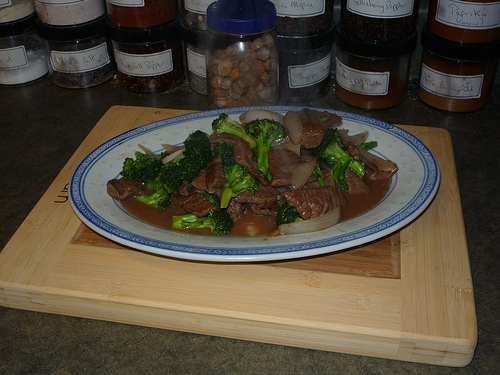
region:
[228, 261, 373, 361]
the board is brown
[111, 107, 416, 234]
the food is cooked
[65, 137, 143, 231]
the plate is blue and white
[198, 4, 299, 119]
the jar is closed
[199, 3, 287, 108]
the jar is full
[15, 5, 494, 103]
there are many jars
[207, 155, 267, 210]
the veggie is green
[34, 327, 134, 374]
the counter is green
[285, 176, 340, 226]
the beef is brown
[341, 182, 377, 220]
the liquid is brown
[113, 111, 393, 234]
food, meat and vegetables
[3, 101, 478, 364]
wooden cutting board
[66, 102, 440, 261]
white plate with blue trim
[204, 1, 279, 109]
jar with orange rocks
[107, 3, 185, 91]
jar with red lid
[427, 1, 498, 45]
jar with label that says paprika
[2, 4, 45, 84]
jar of salt on the far left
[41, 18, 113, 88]
jar second from left that says black salt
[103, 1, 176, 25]
jar third from right with red powder inside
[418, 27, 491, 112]
bottom jar on the far right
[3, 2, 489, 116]
a row of spice jars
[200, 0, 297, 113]
a clear mason jar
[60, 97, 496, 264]
a meal is placed on a blue and white dish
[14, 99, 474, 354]
a plate of food is placed on a cutting board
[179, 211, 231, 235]
piece of broccoli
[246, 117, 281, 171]
piece of broccoli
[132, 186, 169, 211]
piece of broccoli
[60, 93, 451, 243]
a plate of beef and broccoli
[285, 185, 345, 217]
a slice of beef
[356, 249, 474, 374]
part of wooden cutting board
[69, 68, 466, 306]
a plate of broccoli and beef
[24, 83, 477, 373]
a plate on a cutting board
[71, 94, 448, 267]
a blue and white china plate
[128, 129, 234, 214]
a few pieces of broccoli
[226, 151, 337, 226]
thin slices of cooked beef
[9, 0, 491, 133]
rows of round jars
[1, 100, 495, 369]
a square cutting board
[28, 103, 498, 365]
a two toned board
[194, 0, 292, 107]
a jar with blue lid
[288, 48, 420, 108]
some old white labels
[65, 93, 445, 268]
a blue and white dinner plate with food on it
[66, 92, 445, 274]
beef and broccoli on a plate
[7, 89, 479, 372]
wooden board under a plate of food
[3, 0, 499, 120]
jars of spices are all labelled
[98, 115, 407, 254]
beef and broccoli in gravy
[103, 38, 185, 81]
white hand written label on a jar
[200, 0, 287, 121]
jar with a blue lid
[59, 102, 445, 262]
blue decorative edge of a white plate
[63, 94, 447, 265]
circular china dinner plate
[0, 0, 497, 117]
jars are stacked two-tier